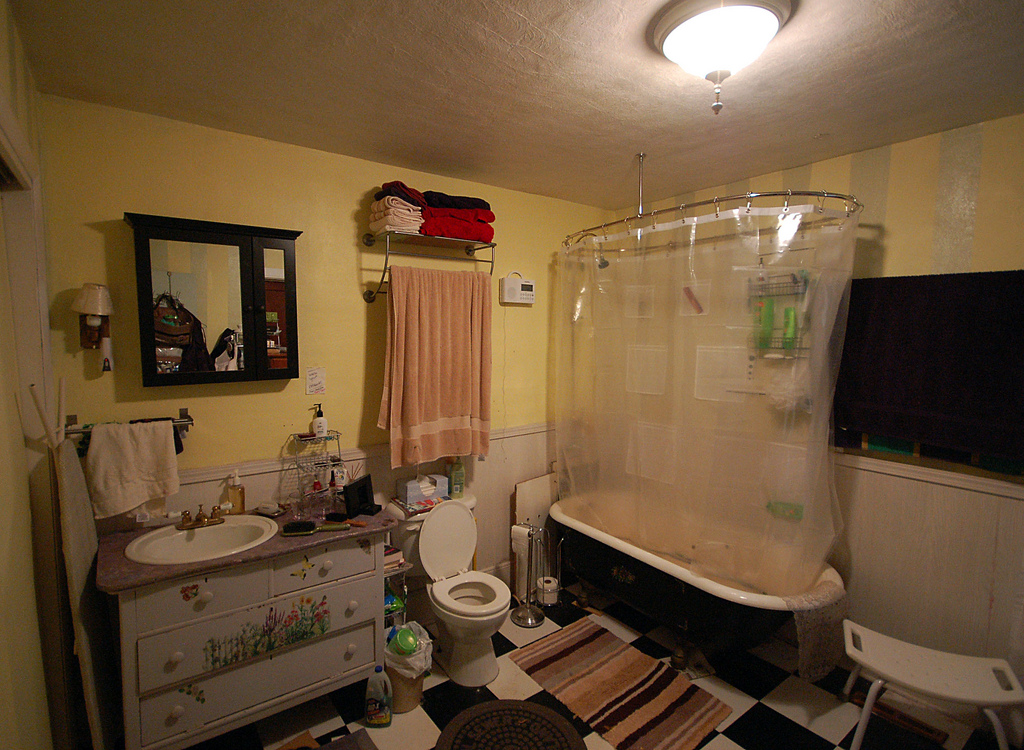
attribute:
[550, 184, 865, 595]
shower curtain — clear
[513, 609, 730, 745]
rug — striped